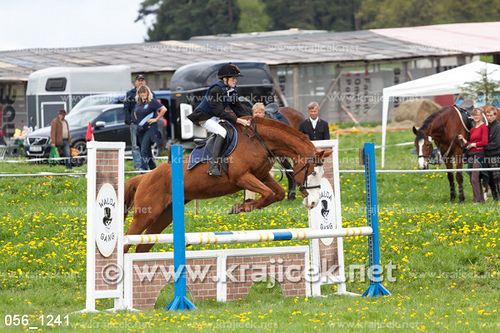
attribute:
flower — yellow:
[425, 251, 432, 256]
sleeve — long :
[478, 120, 485, 147]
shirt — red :
[468, 124, 490, 152]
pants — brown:
[466, 153, 483, 198]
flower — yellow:
[421, 244, 435, 255]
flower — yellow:
[441, 227, 453, 233]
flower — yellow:
[469, 224, 486, 231]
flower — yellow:
[487, 222, 498, 232]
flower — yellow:
[432, 210, 444, 215]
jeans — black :
[182, 110, 241, 167]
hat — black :
[202, 54, 250, 81]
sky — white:
[3, 7, 165, 62]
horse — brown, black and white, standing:
[411, 102, 498, 204]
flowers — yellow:
[360, 175, 492, 269]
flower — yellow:
[3, 210, 88, 275]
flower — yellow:
[227, 312, 250, 322]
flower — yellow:
[446, 224, 493, 251]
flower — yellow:
[5, 210, 66, 233]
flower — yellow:
[376, 207, 418, 232]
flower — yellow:
[202, 220, 299, 235]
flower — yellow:
[178, 312, 193, 324]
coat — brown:
[45, 111, 75, 149]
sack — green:
[43, 140, 62, 170]